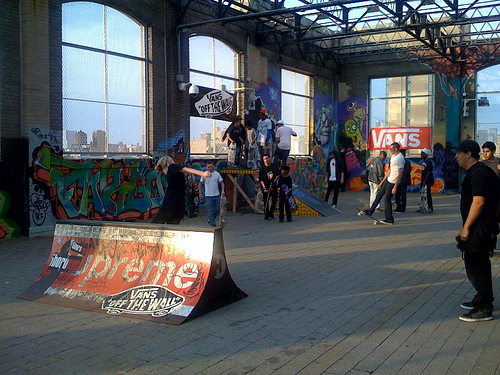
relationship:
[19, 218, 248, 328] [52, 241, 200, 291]
ramp with supreme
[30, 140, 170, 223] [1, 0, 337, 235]
graffiti on wall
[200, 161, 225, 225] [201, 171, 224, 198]
boy in shirt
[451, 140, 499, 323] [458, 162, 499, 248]
man in shirt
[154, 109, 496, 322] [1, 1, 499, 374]
people in skatepark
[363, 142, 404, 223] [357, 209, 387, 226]
man on board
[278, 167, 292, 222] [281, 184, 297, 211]
kid with board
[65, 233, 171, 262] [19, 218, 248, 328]
graffiti on ramp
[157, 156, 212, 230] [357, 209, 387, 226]
boy on board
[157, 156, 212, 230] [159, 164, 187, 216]
boy in shirt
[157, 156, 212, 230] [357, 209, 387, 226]
boy with board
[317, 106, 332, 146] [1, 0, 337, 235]
face on wall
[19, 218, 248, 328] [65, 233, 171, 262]
ramp with graffiti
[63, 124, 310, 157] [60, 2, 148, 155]
city behind windows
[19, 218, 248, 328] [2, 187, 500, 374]
ramp on floor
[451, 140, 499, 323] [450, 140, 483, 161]
man with hat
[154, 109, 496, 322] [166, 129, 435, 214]
people enjoying friends